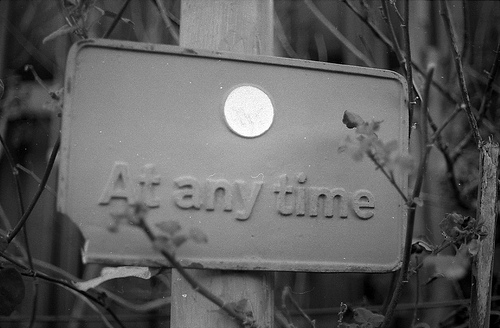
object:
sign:
[54, 36, 410, 274]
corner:
[53, 209, 88, 264]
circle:
[222, 84, 274, 139]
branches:
[343, 1, 500, 327]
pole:
[178, 0, 274, 57]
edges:
[59, 37, 76, 130]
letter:
[95, 162, 139, 204]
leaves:
[432, 214, 488, 248]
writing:
[170, 173, 378, 221]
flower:
[413, 214, 489, 264]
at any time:
[97, 162, 378, 221]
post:
[168, 1, 280, 327]